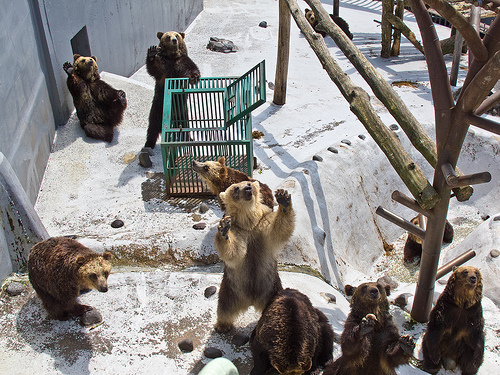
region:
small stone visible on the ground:
[176, 338, 196, 356]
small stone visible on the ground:
[177, 338, 202, 367]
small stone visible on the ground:
[182, 337, 193, 354]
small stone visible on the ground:
[172, 332, 197, 362]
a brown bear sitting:
[26, 236, 113, 317]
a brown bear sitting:
[63, 54, 130, 146]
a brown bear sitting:
[252, 287, 323, 371]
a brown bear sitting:
[335, 279, 410, 374]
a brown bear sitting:
[425, 261, 489, 373]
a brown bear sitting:
[185, 159, 273, 204]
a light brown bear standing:
[199, 173, 291, 331]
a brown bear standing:
[143, 28, 203, 156]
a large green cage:
[149, 61, 269, 196]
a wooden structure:
[265, 1, 497, 324]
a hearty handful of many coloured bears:
[17, 18, 489, 373]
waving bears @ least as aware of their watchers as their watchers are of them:
[18, 27, 489, 374]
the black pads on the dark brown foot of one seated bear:
[59, 58, 78, 79]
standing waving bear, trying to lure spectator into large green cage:
[141, 22, 206, 162]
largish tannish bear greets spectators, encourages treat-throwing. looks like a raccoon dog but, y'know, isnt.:
[201, 176, 299, 341]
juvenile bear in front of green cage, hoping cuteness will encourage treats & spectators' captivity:
[185, 155, 276, 224]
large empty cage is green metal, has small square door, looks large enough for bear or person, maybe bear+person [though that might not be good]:
[157, 56, 274, 203]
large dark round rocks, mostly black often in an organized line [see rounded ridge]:
[153, 112, 426, 372]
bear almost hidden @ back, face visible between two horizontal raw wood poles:
[299, 5, 356, 49]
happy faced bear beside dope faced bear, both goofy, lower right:
[348, 264, 486, 319]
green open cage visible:
[153, 76, 262, 192]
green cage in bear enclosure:
[149, 51, 308, 207]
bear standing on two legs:
[162, 182, 323, 318]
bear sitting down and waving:
[54, 44, 105, 138]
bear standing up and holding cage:
[142, 28, 212, 159]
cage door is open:
[193, 65, 286, 146]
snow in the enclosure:
[306, 118, 377, 212]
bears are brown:
[432, 274, 484, 372]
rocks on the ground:
[178, 282, 234, 372]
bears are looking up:
[354, 254, 487, 306]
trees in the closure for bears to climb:
[281, 11, 498, 197]